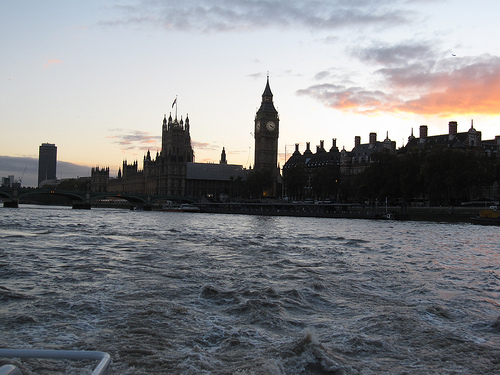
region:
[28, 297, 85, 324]
body of a water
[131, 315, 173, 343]
body of a water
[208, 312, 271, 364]
body of a water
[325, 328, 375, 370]
body of a water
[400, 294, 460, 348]
body of a water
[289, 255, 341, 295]
body of a water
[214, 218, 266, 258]
body of a water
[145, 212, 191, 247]
body of a water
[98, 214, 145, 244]
body of a water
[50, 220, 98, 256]
body of a water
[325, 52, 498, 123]
Thick orange colored clouds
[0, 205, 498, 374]
Expanse of calm water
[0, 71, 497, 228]
Buildings by the shore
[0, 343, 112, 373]
Grey pipe with a square curve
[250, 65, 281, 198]
Tall building with large clocks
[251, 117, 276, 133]
Clocks with round faces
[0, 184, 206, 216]
Bridge across the water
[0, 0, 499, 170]
Dull blue sky with orange patches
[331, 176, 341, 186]
Small light in the distance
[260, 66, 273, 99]
Sharp tip of a building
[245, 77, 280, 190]
Big Ben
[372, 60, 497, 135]
an orange fluffy cloud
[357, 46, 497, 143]
the sun is setting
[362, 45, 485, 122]
the cloud turns orange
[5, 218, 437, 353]
a body of water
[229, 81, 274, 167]
clocktower on the other side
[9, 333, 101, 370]
a metal pole in the corner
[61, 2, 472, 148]
few clouds in the sky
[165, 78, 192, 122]
a flag atop the building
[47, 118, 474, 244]
town on the other side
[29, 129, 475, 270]
taken across the lake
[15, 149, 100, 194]
mountains in the distance